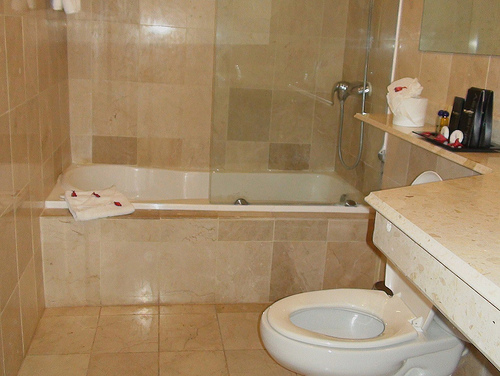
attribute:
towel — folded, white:
[64, 185, 138, 223]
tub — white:
[38, 150, 383, 312]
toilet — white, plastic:
[255, 168, 473, 375]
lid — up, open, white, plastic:
[381, 167, 447, 330]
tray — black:
[412, 124, 499, 155]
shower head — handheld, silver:
[326, 75, 355, 108]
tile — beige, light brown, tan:
[19, 299, 329, 375]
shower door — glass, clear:
[210, 2, 401, 209]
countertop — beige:
[358, 173, 500, 318]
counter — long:
[363, 165, 498, 372]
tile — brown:
[2, 2, 404, 208]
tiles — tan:
[63, 1, 348, 171]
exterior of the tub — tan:
[41, 207, 391, 311]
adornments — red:
[69, 187, 123, 208]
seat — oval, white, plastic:
[262, 284, 415, 352]